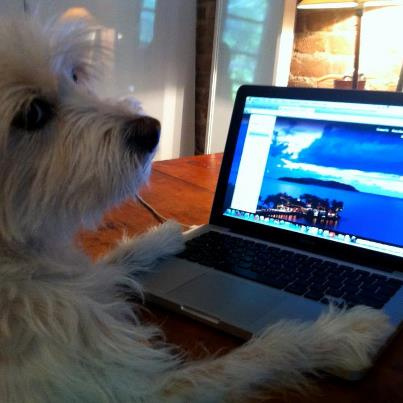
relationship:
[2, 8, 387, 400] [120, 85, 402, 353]
dog using laptop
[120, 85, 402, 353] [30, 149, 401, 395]
laptop on desk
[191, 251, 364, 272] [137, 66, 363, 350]
keyboard on laptop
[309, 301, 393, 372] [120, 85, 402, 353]
paw on laptop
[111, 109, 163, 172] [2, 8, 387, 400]
snout of dog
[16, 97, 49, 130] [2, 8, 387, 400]
eye of dog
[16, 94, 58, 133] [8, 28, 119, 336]
eye of dog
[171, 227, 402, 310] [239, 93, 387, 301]
keyboard on laptop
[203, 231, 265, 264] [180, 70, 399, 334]
key on laptop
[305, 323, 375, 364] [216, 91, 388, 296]
paws on laptop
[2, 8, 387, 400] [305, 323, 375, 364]
dog with paws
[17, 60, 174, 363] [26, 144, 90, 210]
dog with fur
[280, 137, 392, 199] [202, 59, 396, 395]
scene on laptop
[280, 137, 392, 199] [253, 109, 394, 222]
scene on screen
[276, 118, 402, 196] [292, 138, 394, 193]
clouds in picture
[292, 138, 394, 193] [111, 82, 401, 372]
picture on computer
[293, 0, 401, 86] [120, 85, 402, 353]
lamp behind laptop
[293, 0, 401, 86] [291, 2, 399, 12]
lamp has shade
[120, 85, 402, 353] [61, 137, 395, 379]
laptop on table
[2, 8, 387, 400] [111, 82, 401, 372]
dog using computer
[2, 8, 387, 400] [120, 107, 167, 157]
dog has nose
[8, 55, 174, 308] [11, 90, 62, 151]
dog has eye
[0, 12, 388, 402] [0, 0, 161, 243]
white dog has head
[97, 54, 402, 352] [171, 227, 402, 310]
laptop has keyboard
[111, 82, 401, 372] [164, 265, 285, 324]
computer has mouse pad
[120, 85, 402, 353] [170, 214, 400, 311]
laptop has keyboard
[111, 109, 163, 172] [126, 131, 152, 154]
snout has nostril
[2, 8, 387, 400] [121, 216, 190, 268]
dog has paw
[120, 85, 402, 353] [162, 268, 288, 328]
laptop has mouse pad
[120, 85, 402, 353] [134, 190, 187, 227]
laptop has black cord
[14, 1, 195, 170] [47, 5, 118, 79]
wall has reflection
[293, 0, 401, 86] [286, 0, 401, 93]
lamp on wall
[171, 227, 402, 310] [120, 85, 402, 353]
keyboard on laptop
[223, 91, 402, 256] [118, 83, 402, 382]
screen on laptop